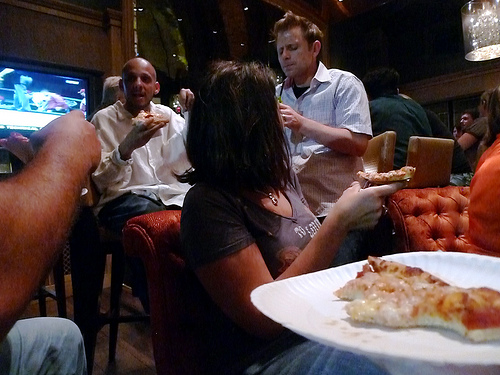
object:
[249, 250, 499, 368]
white plate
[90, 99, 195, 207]
shirt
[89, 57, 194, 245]
man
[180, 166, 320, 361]
shirt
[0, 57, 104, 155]
tv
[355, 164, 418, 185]
pizza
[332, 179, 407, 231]
hand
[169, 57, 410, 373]
woman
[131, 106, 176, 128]
pizza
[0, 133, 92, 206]
pizza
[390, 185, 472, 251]
chair back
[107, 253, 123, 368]
stool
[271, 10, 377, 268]
man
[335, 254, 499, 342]
pizza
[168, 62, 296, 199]
hair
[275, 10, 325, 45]
hair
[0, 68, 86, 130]
match